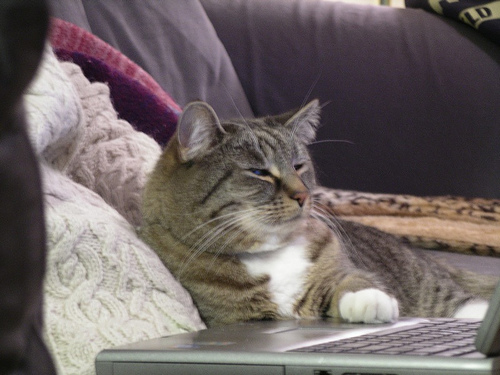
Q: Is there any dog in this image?
A: No, there are no dogs.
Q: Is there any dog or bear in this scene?
A: No, there are no dogs or bears.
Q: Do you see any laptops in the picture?
A: Yes, there is a laptop.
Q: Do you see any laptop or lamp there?
A: Yes, there is a laptop.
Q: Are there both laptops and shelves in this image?
A: No, there is a laptop but no shelves.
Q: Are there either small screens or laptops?
A: Yes, there is a small laptop.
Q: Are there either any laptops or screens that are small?
A: Yes, the laptop is small.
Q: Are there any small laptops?
A: Yes, there is a small laptop.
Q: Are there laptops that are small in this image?
A: Yes, there is a small laptop.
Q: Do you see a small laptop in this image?
A: Yes, there is a small laptop.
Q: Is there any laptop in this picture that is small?
A: Yes, there is a laptop that is small.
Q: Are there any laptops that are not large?
A: Yes, there is a small laptop.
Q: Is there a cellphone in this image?
A: No, there are no cell phones.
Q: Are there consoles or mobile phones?
A: No, there are no mobile phones or consoles.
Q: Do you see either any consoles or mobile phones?
A: No, there are no mobile phones or consoles.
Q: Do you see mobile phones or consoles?
A: No, there are no mobile phones or consoles.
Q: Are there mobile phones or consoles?
A: No, there are no mobile phones or consoles.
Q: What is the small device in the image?
A: The device is a laptop.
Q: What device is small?
A: The device is a laptop.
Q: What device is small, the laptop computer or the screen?
A: The laptop computer is small.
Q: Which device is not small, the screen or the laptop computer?
A: The screen is not small.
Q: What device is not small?
A: The device is a screen.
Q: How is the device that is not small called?
A: The device is a screen.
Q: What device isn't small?
A: The device is a screen.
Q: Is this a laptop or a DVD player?
A: This is a laptop.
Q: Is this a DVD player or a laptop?
A: This is a laptop.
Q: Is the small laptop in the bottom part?
A: Yes, the laptop computer is in the bottom of the image.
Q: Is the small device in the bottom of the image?
A: Yes, the laptop computer is in the bottom of the image.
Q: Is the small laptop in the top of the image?
A: No, the laptop is in the bottom of the image.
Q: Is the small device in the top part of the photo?
A: No, the laptop is in the bottom of the image.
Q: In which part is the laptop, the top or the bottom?
A: The laptop is in the bottom of the image.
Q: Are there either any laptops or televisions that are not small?
A: No, there is a laptop but it is small.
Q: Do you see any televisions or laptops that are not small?
A: No, there is a laptop but it is small.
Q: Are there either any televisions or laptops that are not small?
A: No, there is a laptop but it is small.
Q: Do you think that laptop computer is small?
A: Yes, the laptop computer is small.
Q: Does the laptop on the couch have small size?
A: Yes, the laptop is small.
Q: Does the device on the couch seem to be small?
A: Yes, the laptop is small.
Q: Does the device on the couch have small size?
A: Yes, the laptop is small.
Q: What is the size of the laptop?
A: The laptop is small.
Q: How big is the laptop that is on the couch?
A: The laptop is small.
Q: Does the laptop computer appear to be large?
A: No, the laptop computer is small.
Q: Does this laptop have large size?
A: No, the laptop is small.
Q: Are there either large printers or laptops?
A: No, there is a laptop but it is small.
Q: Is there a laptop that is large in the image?
A: No, there is a laptop but it is small.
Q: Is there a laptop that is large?
A: No, there is a laptop but it is small.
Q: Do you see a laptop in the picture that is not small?
A: No, there is a laptop but it is small.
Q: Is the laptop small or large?
A: The laptop is small.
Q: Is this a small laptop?
A: Yes, this is a small laptop.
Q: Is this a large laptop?
A: No, this is a small laptop.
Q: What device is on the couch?
A: The device is a laptop.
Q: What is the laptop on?
A: The laptop is on the couch.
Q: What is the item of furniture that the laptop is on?
A: The piece of furniture is a couch.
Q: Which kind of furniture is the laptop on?
A: The laptop is on the couch.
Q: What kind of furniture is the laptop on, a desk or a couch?
A: The laptop is on a couch.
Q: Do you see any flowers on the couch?
A: No, there is a laptop on the couch.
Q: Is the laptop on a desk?
A: No, the laptop is on the couch.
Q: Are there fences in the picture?
A: No, there are no fences.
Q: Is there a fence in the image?
A: No, there are no fences.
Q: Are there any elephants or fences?
A: No, there are no fences or elephants.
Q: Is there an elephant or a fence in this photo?
A: No, there are no fences or elephants.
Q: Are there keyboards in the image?
A: Yes, there is a keyboard.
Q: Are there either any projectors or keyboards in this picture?
A: Yes, there is a keyboard.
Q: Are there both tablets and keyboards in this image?
A: No, there is a keyboard but no tablets.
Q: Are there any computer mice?
A: No, there are no computer mice.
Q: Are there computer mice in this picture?
A: No, there are no computer mice.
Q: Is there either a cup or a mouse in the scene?
A: No, there are no computer mice or cups.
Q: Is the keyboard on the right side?
A: Yes, the keyboard is on the right of the image.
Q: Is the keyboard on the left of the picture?
A: No, the keyboard is on the right of the image.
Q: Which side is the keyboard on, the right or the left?
A: The keyboard is on the right of the image.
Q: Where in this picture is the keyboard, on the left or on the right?
A: The keyboard is on the right of the image.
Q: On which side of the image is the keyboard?
A: The keyboard is on the right of the image.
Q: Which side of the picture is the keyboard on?
A: The keyboard is on the right of the image.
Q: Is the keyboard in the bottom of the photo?
A: Yes, the keyboard is in the bottom of the image.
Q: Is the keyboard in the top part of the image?
A: No, the keyboard is in the bottom of the image.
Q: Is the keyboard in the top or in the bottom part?
A: The keyboard is in the bottom of the image.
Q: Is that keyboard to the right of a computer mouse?
A: No, the keyboard is to the right of the blanket.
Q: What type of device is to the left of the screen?
A: The device is a keyboard.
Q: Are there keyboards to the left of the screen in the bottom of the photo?
A: Yes, there is a keyboard to the left of the screen.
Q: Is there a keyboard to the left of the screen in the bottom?
A: Yes, there is a keyboard to the left of the screen.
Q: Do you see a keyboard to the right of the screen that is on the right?
A: No, the keyboard is to the left of the screen.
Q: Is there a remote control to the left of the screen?
A: No, there is a keyboard to the left of the screen.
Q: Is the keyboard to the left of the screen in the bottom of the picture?
A: Yes, the keyboard is to the left of the screen.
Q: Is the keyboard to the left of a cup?
A: No, the keyboard is to the left of the screen.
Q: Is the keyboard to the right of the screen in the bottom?
A: No, the keyboard is to the left of the screen.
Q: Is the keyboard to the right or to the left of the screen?
A: The keyboard is to the left of the screen.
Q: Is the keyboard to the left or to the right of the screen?
A: The keyboard is to the left of the screen.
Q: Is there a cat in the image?
A: Yes, there is a cat.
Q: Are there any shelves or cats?
A: Yes, there is a cat.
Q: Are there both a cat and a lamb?
A: No, there is a cat but no lambs.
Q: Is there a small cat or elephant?
A: Yes, there is a small cat.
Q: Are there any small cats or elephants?
A: Yes, there is a small cat.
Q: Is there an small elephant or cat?
A: Yes, there is a small cat.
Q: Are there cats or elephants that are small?
A: Yes, the cat is small.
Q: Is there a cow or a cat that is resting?
A: Yes, the cat is resting.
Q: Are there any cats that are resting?
A: Yes, there is a cat that is resting.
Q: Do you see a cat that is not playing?
A: Yes, there is a cat that is resting .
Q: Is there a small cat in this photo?
A: Yes, there is a small cat.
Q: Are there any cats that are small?
A: Yes, there is a cat that is small.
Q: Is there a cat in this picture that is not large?
A: Yes, there is a small cat.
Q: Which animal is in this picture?
A: The animal is a cat.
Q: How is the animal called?
A: The animal is a cat.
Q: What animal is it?
A: The animal is a cat.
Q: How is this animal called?
A: This is a cat.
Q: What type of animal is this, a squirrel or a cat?
A: This is a cat.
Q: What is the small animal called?
A: The animal is a cat.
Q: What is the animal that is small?
A: The animal is a cat.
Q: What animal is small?
A: The animal is a cat.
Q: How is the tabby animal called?
A: The animal is a cat.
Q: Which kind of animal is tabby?
A: The animal is a cat.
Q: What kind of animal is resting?
A: The animal is a cat.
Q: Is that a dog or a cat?
A: That is a cat.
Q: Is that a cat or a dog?
A: That is a cat.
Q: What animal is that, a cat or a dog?
A: That is a cat.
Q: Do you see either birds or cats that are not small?
A: No, there is a cat but it is small.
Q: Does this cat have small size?
A: Yes, the cat is small.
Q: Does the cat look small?
A: Yes, the cat is small.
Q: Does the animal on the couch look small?
A: Yes, the cat is small.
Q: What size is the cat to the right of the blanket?
A: The cat is small.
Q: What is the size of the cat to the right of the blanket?
A: The cat is small.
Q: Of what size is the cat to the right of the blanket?
A: The cat is small.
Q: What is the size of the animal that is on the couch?
A: The cat is small.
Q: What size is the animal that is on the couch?
A: The cat is small.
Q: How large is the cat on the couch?
A: The cat is small.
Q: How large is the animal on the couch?
A: The cat is small.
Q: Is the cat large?
A: No, the cat is small.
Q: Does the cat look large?
A: No, the cat is small.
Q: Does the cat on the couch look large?
A: No, the cat is small.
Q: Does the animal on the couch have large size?
A: No, the cat is small.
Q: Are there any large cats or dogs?
A: No, there is a cat but it is small.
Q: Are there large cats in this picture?
A: No, there is a cat but it is small.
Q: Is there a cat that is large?
A: No, there is a cat but it is small.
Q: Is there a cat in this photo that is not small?
A: No, there is a cat but it is small.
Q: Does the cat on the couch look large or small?
A: The cat is small.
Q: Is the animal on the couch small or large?
A: The cat is small.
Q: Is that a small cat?
A: Yes, that is a small cat.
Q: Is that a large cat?
A: No, that is a small cat.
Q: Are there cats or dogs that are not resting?
A: No, there is a cat but it is resting.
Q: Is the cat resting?
A: Yes, the cat is resting.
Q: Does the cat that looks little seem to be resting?
A: Yes, the cat is resting.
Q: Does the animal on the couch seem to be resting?
A: Yes, the cat is resting.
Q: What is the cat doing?
A: The cat is resting.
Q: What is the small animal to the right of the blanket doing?
A: The cat is resting.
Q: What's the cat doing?
A: The cat is resting.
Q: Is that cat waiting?
A: No, the cat is resting.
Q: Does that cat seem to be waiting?
A: No, the cat is resting.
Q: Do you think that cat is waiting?
A: No, the cat is resting.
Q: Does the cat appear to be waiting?
A: No, the cat is resting.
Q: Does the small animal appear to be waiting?
A: No, the cat is resting.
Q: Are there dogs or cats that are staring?
A: No, there is a cat but it is resting.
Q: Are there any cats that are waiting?
A: No, there is a cat but it is resting.